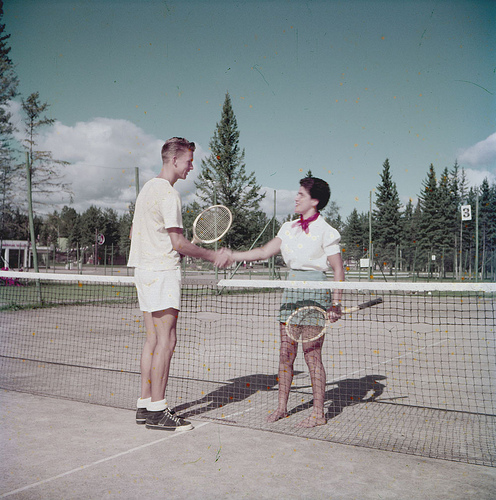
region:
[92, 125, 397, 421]
Lady and man shaking hands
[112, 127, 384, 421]
Lady and man playing tennis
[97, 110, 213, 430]
Man wearing white shirt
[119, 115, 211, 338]
Man wearing white shorts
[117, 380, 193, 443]
Man wearing black tennis shoes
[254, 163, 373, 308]
Woman wearing red scarf around neck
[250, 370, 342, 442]
Lady is bare foot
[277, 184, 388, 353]
Lady is holding tennis racket in left hand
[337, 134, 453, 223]
Pine trees against a blue sky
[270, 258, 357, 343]
Lady is wearing blue skirt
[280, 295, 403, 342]
tennis racket in the female player's hand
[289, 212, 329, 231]
red scarf around the woman's neck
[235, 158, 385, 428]
female tennis player holding a racket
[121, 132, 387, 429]
tennis players shaking hands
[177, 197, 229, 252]
tennis racket in the man's hand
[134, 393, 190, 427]
pair of black shoes on the male tennis player's feet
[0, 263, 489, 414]
long black tennis net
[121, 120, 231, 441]
male tennis player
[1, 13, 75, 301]
very tall trees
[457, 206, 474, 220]
the number 3 printed on a sign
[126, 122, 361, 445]
Two people shaking hands.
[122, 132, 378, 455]
Tow people standing at net.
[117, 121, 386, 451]
Two people holding rackets.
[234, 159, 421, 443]
The woman is barefoot.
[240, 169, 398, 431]
Woman has short hair.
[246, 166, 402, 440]
Scarf around woman's neck.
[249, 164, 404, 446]
The scarf is red.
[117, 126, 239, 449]
Man wearing tennis shoes.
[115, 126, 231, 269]
Man has short hair.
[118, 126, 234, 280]
Man's hair is blonde.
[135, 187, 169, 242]
Person wearing white shirt.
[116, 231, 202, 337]
Person wearing white shorts.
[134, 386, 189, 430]
Person wearing white socks.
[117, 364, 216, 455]
Person wearing black shoes.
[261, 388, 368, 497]
Person is bare foot.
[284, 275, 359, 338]
Person wearing blue skirt.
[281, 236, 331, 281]
Person wearing white shirt.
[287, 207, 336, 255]
Red scarf around person's neck.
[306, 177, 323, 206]
Person has brown hair.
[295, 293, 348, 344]
Person holding tennis racket.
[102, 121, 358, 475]
Two people playing badminton